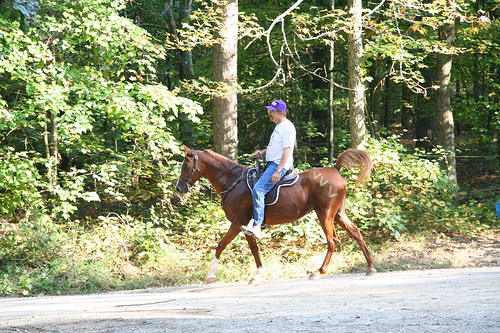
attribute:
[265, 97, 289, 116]
cap — blue, purple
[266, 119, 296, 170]
shirt — short-sleeved, white, large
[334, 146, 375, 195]
tail — brown, raised, erect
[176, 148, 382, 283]
horse — brown, walking, running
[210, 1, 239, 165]
trunk — tall, large, thick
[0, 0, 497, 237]
leaves — green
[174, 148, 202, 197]
head — brown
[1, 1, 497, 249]
forest — thick, dense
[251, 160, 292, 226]
jeans — blue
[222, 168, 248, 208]
harness — black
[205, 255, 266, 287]
feet — white